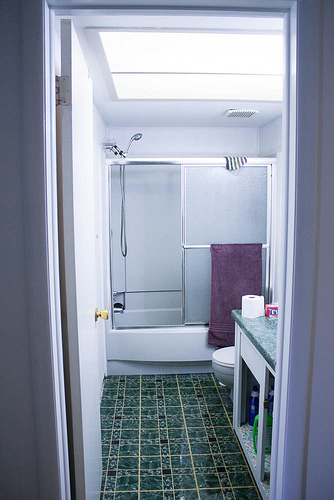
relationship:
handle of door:
[93, 307, 109, 320] [57, 18, 104, 498]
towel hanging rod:
[206, 243, 263, 347] [184, 156, 273, 165]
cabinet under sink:
[222, 314, 279, 491] [229, 306, 276, 369]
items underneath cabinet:
[249, 412, 276, 478] [237, 354, 271, 482]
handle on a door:
[95, 308, 109, 322] [57, 18, 104, 498]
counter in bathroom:
[229, 278, 289, 385] [66, 7, 288, 497]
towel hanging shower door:
[207, 243, 261, 345] [179, 157, 269, 327]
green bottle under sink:
[250, 402, 278, 460] [264, 320, 281, 376]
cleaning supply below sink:
[248, 385, 260, 425] [238, 360, 277, 482]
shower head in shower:
[121, 131, 145, 156] [108, 129, 270, 373]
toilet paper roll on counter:
[240, 293, 265, 317] [232, 305, 276, 366]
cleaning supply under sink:
[249, 385, 259, 426] [231, 307, 279, 497]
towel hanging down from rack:
[207, 243, 261, 345] [182, 243, 268, 246]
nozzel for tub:
[112, 300, 125, 316] [109, 288, 256, 370]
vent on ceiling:
[222, 107, 262, 119] [212, 93, 259, 131]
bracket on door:
[53, 71, 70, 105] [57, 18, 104, 498]